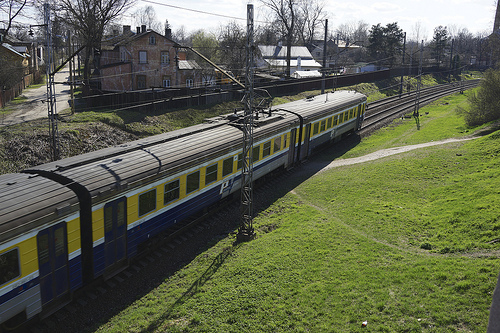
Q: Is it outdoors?
A: Yes, it is outdoors.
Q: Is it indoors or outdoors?
A: It is outdoors.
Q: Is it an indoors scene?
A: No, it is outdoors.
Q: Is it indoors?
A: No, it is outdoors.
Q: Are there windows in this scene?
A: Yes, there is a window.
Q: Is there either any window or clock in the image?
A: Yes, there is a window.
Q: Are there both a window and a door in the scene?
A: Yes, there are both a window and a door.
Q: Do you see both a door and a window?
A: Yes, there are both a window and a door.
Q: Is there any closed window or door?
A: Yes, there is a closed window.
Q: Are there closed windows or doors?
A: Yes, there is a closed window.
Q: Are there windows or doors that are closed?
A: Yes, the window is closed.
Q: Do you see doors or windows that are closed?
A: Yes, the window is closed.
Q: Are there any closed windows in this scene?
A: Yes, there is a closed window.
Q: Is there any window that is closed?
A: Yes, there is a window that is closed.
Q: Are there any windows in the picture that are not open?
A: Yes, there is an closed window.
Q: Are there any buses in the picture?
A: No, there are no buses.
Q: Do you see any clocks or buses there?
A: No, there are no buses or clocks.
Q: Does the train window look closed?
A: Yes, the window is closed.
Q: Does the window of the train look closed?
A: Yes, the window is closed.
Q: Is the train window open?
A: No, the window is closed.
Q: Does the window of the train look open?
A: No, the window is closed.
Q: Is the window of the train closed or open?
A: The window is closed.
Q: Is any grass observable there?
A: Yes, there is grass.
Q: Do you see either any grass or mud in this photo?
A: Yes, there is grass.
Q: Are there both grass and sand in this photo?
A: No, there is grass but no sand.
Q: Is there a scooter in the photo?
A: No, there are no scooters.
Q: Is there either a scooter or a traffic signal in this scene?
A: No, there are no scooters or traffic lights.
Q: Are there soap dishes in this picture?
A: No, there are no soap dishes.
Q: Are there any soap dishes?
A: No, there are no soap dishes.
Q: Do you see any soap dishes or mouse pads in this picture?
A: No, there are no soap dishes or mouse pads.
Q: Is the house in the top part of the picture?
A: Yes, the house is in the top of the image.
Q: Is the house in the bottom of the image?
A: No, the house is in the top of the image.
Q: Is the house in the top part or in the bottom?
A: The house is in the top of the image.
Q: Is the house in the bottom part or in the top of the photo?
A: The house is in the top of the image.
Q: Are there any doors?
A: Yes, there is a door.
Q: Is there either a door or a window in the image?
A: Yes, there is a door.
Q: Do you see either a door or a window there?
A: Yes, there is a door.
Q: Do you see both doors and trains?
A: Yes, there are both a door and a train.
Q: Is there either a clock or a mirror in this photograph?
A: No, there are no clocks or mirrors.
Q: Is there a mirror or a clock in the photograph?
A: No, there are no clocks or mirrors.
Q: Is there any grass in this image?
A: Yes, there is grass.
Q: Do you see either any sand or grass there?
A: Yes, there is grass.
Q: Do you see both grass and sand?
A: No, there is grass but no sand.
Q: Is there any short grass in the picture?
A: Yes, there is short grass.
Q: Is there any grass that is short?
A: Yes, there is grass that is short.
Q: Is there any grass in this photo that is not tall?
A: Yes, there is short grass.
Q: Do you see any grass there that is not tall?
A: Yes, there is short grass.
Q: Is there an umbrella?
A: No, there are no umbrellas.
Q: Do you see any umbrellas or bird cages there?
A: No, there are no umbrellas or bird cages.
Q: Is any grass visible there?
A: Yes, there is grass.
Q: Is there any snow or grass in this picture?
A: Yes, there is grass.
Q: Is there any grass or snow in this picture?
A: Yes, there is grass.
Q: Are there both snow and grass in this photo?
A: No, there is grass but no snow.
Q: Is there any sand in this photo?
A: No, there is no sand.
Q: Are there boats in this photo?
A: No, there are no boats.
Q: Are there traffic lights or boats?
A: No, there are no boats or traffic lights.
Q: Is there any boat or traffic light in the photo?
A: No, there are no boats or traffic lights.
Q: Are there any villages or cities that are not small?
A: No, there is a city but it is small.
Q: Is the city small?
A: Yes, the city is small.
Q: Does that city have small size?
A: Yes, the city is small.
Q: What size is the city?
A: The city is small.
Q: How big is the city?
A: The city is small.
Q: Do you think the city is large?
A: No, the city is small.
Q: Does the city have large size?
A: No, the city is small.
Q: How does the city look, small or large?
A: The city is small.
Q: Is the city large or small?
A: The city is small.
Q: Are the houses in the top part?
A: Yes, the houses are in the top of the image.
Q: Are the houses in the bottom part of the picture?
A: No, the houses are in the top of the image.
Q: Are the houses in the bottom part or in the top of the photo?
A: The houses are in the top of the image.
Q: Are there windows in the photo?
A: Yes, there are windows.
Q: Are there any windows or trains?
A: Yes, there are windows.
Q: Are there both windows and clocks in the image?
A: No, there are windows but no clocks.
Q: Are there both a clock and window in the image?
A: No, there are windows but no clocks.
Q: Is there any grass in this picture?
A: Yes, there is grass.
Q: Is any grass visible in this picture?
A: Yes, there is grass.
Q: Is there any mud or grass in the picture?
A: Yes, there is grass.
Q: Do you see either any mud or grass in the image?
A: Yes, there is grass.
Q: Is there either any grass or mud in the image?
A: Yes, there is grass.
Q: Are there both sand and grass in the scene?
A: No, there is grass but no sand.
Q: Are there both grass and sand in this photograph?
A: No, there is grass but no sand.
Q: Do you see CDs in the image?
A: No, there are no cds.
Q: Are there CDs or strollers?
A: No, there are no CDs or strollers.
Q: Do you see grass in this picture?
A: Yes, there is grass.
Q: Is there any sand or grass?
A: Yes, there is grass.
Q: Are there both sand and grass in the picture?
A: No, there is grass but no sand.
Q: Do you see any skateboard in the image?
A: No, there are no skateboards.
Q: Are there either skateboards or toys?
A: No, there are no skateboards or toys.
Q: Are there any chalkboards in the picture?
A: No, there are no chalkboards.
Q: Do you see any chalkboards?
A: No, there are no chalkboards.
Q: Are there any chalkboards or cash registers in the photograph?
A: No, there are no chalkboards or cash registers.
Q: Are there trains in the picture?
A: Yes, there is a train.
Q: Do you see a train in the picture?
A: Yes, there is a train.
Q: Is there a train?
A: Yes, there is a train.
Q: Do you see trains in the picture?
A: Yes, there is a train.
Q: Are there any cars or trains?
A: Yes, there is a train.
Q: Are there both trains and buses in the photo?
A: No, there is a train but no buses.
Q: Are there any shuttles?
A: No, there are no shuttles.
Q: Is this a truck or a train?
A: This is a train.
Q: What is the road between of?
A: The road is between the houses.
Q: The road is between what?
A: The road is between the houses.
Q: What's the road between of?
A: The road is between the houses.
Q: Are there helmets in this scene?
A: No, there are no helmets.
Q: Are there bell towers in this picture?
A: No, there are no bell towers.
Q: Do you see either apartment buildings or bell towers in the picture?
A: No, there are no bell towers or apartment buildings.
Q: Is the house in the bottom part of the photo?
A: No, the house is in the top of the image.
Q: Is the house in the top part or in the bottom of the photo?
A: The house is in the top of the image.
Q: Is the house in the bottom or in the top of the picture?
A: The house is in the top of the image.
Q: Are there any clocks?
A: No, there are no clocks.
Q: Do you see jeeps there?
A: No, there are no jeeps.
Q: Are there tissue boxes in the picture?
A: No, there are no tissue boxes.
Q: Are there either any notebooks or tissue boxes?
A: No, there are no tissue boxes or notebooks.